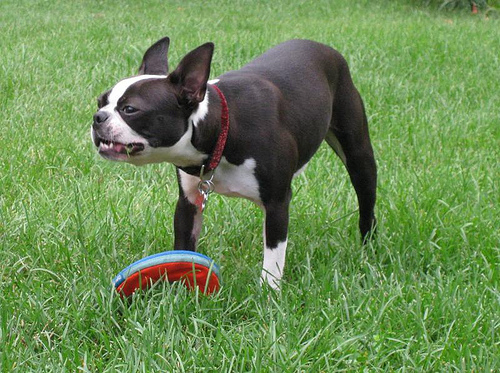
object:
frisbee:
[113, 250, 224, 303]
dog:
[93, 34, 379, 299]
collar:
[194, 83, 231, 220]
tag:
[198, 165, 216, 214]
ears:
[135, 36, 214, 108]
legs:
[172, 91, 382, 291]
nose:
[93, 111, 109, 124]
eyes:
[122, 104, 140, 114]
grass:
[1, 1, 500, 372]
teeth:
[99, 141, 114, 150]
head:
[88, 73, 200, 165]